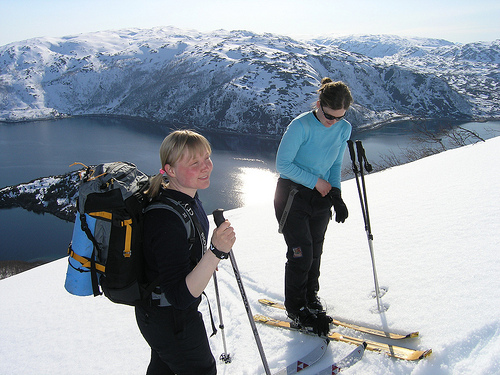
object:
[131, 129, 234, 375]
woman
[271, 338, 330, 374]
silver skis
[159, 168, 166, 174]
band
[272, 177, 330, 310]
jeans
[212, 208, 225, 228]
handle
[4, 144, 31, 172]
water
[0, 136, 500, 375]
snow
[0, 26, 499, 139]
mountain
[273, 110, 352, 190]
shirt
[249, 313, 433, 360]
ski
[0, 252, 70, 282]
ledge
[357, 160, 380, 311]
pole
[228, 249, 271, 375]
pole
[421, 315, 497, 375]
tracks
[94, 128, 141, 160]
water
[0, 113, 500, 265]
lake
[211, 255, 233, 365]
stick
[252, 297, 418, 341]
snowboard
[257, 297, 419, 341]
ski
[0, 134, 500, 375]
ground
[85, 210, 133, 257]
strap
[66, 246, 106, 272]
strap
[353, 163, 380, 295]
ski pole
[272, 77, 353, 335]
woman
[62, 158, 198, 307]
backpack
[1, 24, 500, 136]
snow